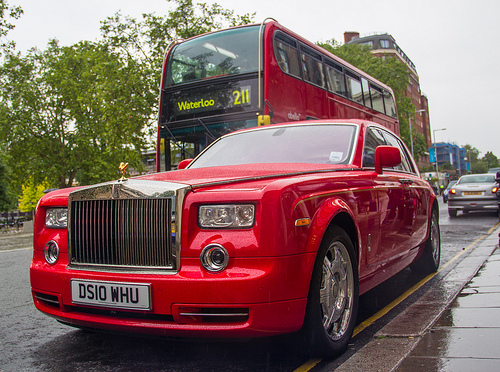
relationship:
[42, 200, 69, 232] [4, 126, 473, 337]
light on car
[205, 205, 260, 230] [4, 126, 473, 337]
light on car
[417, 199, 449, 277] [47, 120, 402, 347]
wheel on car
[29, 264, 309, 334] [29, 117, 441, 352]
bumper on car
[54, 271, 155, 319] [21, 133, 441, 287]
plate on car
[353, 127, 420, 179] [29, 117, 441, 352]
side window on car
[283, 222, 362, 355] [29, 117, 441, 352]
wheel on car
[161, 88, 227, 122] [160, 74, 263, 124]
green waterloo on display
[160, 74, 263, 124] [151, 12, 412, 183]
display on bus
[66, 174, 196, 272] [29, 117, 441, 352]
grill on car